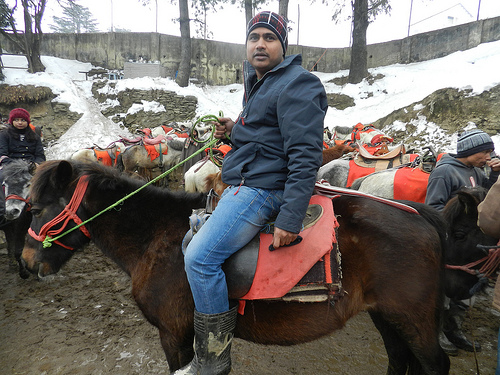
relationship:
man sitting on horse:
[171, 11, 327, 373] [8, 136, 478, 373]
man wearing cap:
[171, 11, 327, 373] [241, 8, 292, 51]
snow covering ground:
[2, 39, 497, 166] [2, 40, 498, 374]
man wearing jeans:
[172, 10, 327, 375] [184, 179, 284, 314]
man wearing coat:
[171, 11, 327, 373] [222, 55, 325, 236]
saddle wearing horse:
[162, 115, 387, 306] [19, 158, 450, 373]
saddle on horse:
[181, 187, 342, 316] [19, 158, 450, 373]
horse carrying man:
[19, 158, 450, 373] [171, 11, 327, 373]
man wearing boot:
[172, 10, 327, 375] [165, 309, 242, 373]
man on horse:
[172, 10, 327, 375] [16, 150, 462, 374]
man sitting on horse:
[172, 10, 327, 375] [18, 155, 480, 357]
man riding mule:
[172, 10, 327, 375] [15, 155, 454, 372]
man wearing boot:
[171, 11, 327, 373] [170, 308, 235, 374]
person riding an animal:
[0, 106, 43, 167] [157, 116, 237, 189]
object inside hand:
[267, 236, 303, 253] [270, 226, 300, 251]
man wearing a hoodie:
[171, 11, 327, 373] [223, 53, 328, 233]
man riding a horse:
[171, 11, 327, 373] [16, 150, 462, 374]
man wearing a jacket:
[171, 11, 327, 373] [214, 48, 329, 233]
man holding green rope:
[172, 10, 327, 375] [44, 113, 222, 250]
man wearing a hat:
[423, 123, 498, 357] [451, 124, 496, 159]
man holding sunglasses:
[172, 10, 327, 375] [269, 234, 304, 253]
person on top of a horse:
[0, 107, 45, 167] [0, 150, 45, 286]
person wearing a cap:
[0, 107, 45, 167] [2, 102, 32, 126]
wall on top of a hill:
[73, 30, 146, 59] [91, 80, 169, 124]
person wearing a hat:
[0, 107, 45, 167] [9, 107, 29, 124]